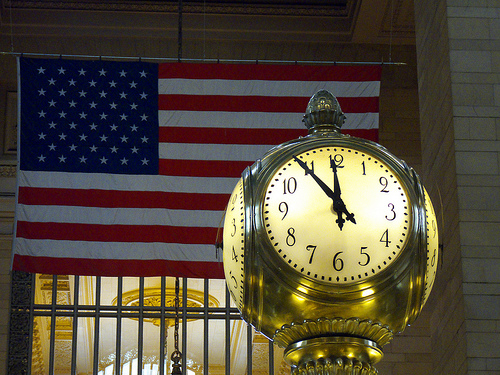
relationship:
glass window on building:
[98, 276, 120, 305] [31, 34, 492, 371]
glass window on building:
[34, 274, 51, 304] [7, 2, 499, 365]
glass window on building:
[57, 268, 74, 303] [7, 2, 499, 365]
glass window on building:
[77, 276, 96, 306] [7, 2, 499, 365]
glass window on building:
[98, 272, 119, 306] [7, 2, 499, 365]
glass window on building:
[144, 272, 160, 304] [7, 2, 499, 365]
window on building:
[202, 279, 229, 308] [7, 2, 499, 365]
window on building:
[34, 277, 101, 374] [22, 196, 494, 364]